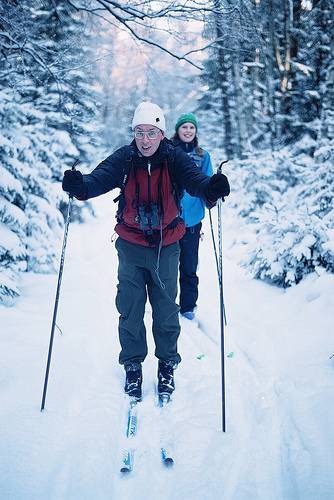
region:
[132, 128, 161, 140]
clear glasses on the skier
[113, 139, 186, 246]
a red vest on the skier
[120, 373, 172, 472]
long thin skis on the skier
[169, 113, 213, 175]
woman behind a male skier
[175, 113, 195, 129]
green sock hat on the woman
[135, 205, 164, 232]
a pair of binoculars on the skier's neck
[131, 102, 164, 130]
a bright white hat on the skier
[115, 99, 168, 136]
the cap is white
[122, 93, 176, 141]
the cap is white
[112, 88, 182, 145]
the cap is white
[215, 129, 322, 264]
bushes covered with snow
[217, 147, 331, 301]
bushes covered with snow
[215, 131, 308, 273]
bushes covered with snow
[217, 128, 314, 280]
bushes covered with snow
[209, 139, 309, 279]
bushes covered with snow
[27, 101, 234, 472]
man on skis holding ski poles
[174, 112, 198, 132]
knit green winter hat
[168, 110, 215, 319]
woman wearing a blue coat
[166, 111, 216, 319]
woman wearing navy blue pants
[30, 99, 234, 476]
two people skiing in the snow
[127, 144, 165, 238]
gray camera with black strap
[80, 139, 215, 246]
puffy black and maroon coat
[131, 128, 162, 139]
metal rim glasses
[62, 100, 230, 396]
man wearing a pair of black gloves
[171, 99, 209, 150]
a woman wearing a green cap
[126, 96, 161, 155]
a man wearing a white winter cap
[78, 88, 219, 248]
man with binoculars hanging around his neck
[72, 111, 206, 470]
man wearing snow skies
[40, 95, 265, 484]
a man and woman out skiing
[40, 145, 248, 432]
man using snow poles while skiing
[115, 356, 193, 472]
snow skis attached to boots.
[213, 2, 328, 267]
snow covered trees and bushes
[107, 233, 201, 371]
man wearing blue pants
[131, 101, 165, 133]
White ski cap.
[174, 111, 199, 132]
Green ski cap.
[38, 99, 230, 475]
Man going down snow covered ski trail.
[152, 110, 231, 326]
Woman standing on snow covered ski trail.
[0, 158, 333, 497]
Snow covered ski trail.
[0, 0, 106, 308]
Trees covered with white snow.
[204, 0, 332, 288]
Trees covered with snow.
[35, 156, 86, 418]
Blue ski pole.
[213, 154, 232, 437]
Blue ski pole.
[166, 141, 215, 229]
Light blue ski jacket.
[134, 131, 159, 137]
glasses on a man's face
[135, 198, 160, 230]
binoculars on a man's chest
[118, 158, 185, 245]
red front of a man's jacket